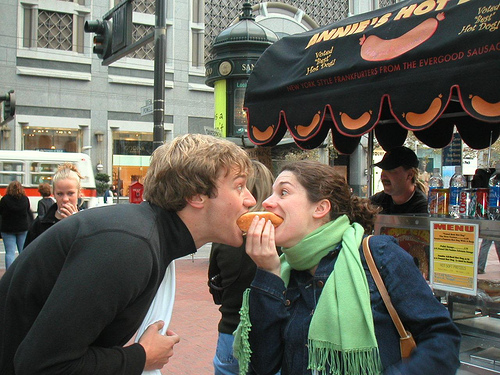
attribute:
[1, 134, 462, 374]
people — posing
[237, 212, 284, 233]
food — shared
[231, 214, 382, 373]
scarf — green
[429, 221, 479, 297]
menu — hanging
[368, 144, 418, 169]
hat — black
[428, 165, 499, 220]
drinks — lined up, different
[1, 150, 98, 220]
vehicle — red, white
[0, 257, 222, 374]
ground — bricks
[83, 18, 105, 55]
traffic light — hanging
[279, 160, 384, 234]
hair — pulled back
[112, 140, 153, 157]
sign — black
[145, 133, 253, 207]
hair — blonde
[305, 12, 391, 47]
annie's — yellow